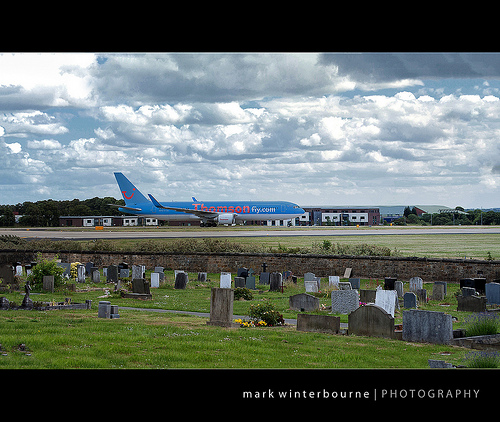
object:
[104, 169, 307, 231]
airplane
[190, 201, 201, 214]
letter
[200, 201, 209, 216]
letter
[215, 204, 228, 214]
letter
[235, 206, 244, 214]
letter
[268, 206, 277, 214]
letter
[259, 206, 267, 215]
letter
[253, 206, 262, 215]
letter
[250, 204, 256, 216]
letter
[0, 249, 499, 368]
cemetery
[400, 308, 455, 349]
headstone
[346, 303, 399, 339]
headstone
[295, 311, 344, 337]
headstone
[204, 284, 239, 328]
headstone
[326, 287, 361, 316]
headstone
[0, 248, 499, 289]
wall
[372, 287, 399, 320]
headstone